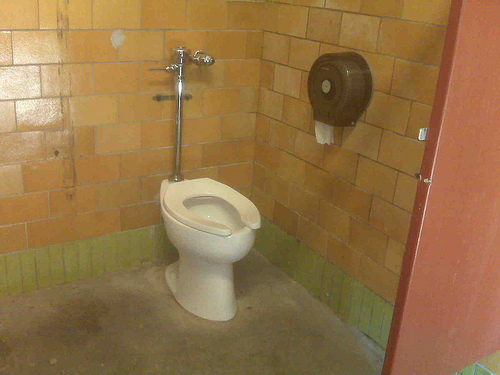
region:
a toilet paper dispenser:
[287, 27, 382, 171]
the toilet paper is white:
[288, 111, 359, 173]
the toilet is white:
[127, 147, 279, 324]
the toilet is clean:
[138, 160, 275, 268]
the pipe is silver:
[132, 15, 227, 172]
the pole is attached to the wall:
[145, 23, 227, 173]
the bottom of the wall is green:
[264, 247, 396, 356]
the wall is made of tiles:
[27, 11, 224, 232]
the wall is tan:
[93, 15, 278, 206]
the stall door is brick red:
[377, 2, 494, 355]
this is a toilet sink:
[161, 170, 270, 337]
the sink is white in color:
[185, 236, 222, 258]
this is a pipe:
[173, 87, 186, 173]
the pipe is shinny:
[175, 80, 186, 112]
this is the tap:
[188, 45, 213, 74]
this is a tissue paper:
[316, 123, 326, 147]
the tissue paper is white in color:
[316, 127, 330, 141]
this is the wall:
[8, 34, 126, 240]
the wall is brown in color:
[13, 20, 102, 159]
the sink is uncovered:
[174, 181, 246, 227]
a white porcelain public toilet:
[144, 43, 262, 323]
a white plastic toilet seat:
[163, 174, 263, 237]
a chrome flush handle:
[144, 64, 165, 74]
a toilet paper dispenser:
[303, 48, 374, 146]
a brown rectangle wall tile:
[346, 215, 388, 264]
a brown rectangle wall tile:
[317, 194, 350, 245]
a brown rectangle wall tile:
[370, 190, 412, 249]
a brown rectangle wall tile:
[356, 150, 394, 210]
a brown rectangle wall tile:
[17, 99, 69, 129]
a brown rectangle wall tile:
[68, 95, 117, 124]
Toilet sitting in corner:
[156, 29, 265, 346]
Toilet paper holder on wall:
[297, 43, 393, 145]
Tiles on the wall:
[293, 213, 467, 341]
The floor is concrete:
[55, 312, 126, 370]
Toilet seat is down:
[161, 176, 262, 244]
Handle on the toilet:
[151, 58, 170, 78]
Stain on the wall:
[88, 27, 139, 54]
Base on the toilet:
[139, 229, 294, 368]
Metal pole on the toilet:
[160, 85, 192, 167]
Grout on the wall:
[352, 147, 363, 186]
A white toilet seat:
[156, 168, 283, 338]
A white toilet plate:
[177, 193, 251, 230]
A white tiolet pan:
[166, 233, 200, 257]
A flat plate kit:
[158, 269, 225, 318]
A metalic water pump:
[169, 48, 226, 170]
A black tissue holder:
[307, 50, 371, 125]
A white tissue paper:
[314, 116, 333, 147]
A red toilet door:
[393, 38, 465, 373]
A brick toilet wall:
[17, 40, 119, 264]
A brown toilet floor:
[105, 315, 223, 373]